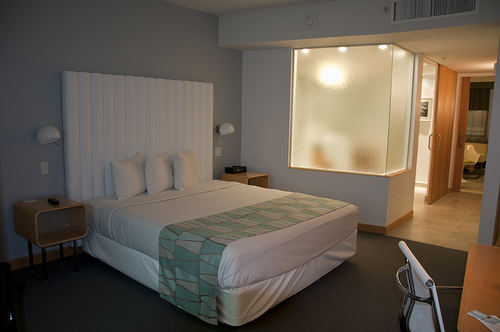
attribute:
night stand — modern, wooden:
[15, 195, 90, 271]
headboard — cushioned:
[62, 71, 214, 204]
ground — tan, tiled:
[425, 154, 466, 193]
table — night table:
[7, 190, 101, 277]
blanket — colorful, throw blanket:
[146, 196, 353, 269]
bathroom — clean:
[290, 46, 436, 208]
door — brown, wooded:
[425, 69, 459, 205]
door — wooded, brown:
[451, 83, 471, 193]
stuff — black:
[223, 160, 250, 177]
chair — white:
[374, 232, 455, 329]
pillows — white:
[106, 150, 202, 202]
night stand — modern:
[14, 193, 94, 276]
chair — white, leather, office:
[393, 238, 464, 330]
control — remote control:
[49, 199, 62, 208]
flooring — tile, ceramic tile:
[388, 187, 482, 251]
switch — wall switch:
[39, 163, 49, 181]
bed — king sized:
[59, 74, 360, 330]